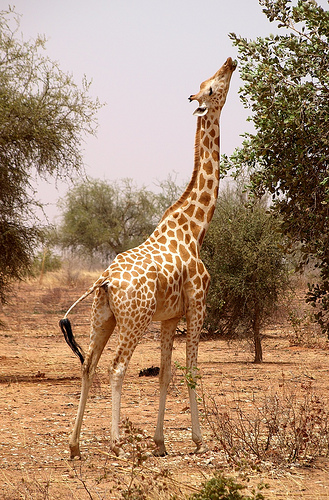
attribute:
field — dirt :
[37, 380, 252, 484]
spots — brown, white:
[136, 242, 194, 306]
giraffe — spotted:
[53, 53, 239, 458]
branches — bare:
[194, 362, 328, 470]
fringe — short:
[170, 117, 199, 214]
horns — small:
[183, 92, 197, 104]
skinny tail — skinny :
[46, 263, 108, 370]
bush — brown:
[209, 391, 326, 472]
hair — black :
[58, 318, 87, 364]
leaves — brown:
[264, 371, 326, 443]